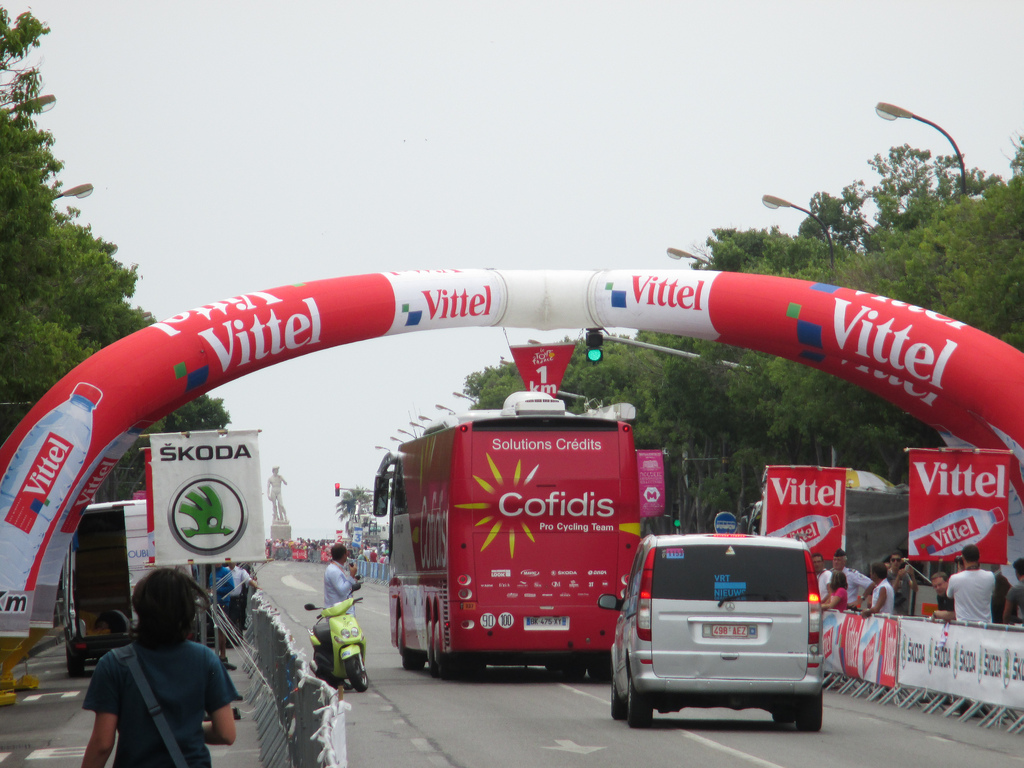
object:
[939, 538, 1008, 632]
man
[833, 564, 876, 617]
shirt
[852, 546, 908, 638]
man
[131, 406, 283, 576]
sign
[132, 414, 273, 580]
business logo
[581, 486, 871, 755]
rear end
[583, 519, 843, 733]
suv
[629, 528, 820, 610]
rear window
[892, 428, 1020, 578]
business logo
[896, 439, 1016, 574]
sign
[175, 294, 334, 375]
logo sign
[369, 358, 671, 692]
bus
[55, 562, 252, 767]
person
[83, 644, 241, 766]
shirt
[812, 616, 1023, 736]
fence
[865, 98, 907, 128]
street lamp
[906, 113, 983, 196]
post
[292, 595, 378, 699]
motorcycle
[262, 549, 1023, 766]
street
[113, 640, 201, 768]
strap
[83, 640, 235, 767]
back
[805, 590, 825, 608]
light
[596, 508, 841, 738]
car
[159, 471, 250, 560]
logo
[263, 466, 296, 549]
statue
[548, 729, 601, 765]
arrow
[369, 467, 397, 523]
mirror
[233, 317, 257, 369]
letter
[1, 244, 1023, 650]
sign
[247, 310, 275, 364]
letter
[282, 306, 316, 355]
letter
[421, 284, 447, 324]
letter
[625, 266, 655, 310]
letter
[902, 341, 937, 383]
letter